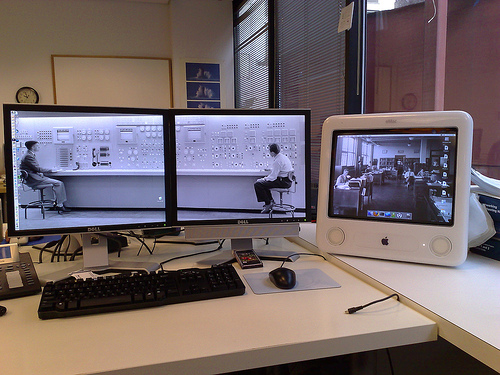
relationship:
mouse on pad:
[270, 269, 294, 288] [244, 267, 338, 292]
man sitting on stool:
[254, 146, 290, 212] [276, 170, 295, 214]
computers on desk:
[6, 104, 472, 267] [1, 234, 500, 372]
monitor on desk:
[316, 121, 482, 262] [1, 234, 500, 372]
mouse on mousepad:
[270, 269, 294, 288] [244, 267, 338, 292]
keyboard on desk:
[38, 266, 241, 316] [1, 234, 500, 372]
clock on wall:
[17, 89, 39, 101] [3, 2, 240, 112]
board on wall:
[52, 57, 173, 107] [3, 2, 240, 112]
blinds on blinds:
[273, 0, 346, 127] [273, 0, 346, 185]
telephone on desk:
[2, 243, 40, 300] [1, 234, 500, 372]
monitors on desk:
[6, 104, 472, 267] [1, 234, 500, 372]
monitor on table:
[173, 111, 303, 223] [1, 234, 500, 372]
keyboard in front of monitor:
[38, 266, 241, 316] [173, 111, 303, 223]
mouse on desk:
[270, 269, 294, 288] [1, 234, 500, 372]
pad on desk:
[244, 267, 338, 292] [1, 234, 500, 372]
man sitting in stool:
[25, 143, 69, 209] [19, 169, 54, 212]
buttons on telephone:
[19, 261, 35, 285] [2, 243, 40, 300]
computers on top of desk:
[6, 104, 472, 267] [1, 234, 500, 372]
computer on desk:
[9, 105, 179, 277] [1, 234, 500, 372]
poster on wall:
[186, 63, 219, 108] [3, 2, 240, 112]